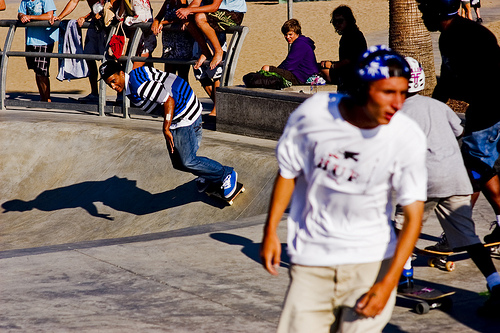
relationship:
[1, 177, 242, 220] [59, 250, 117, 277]
shadow on pavement